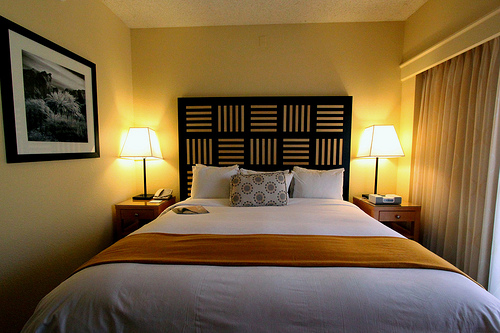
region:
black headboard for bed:
[168, 95, 369, 206]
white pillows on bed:
[161, 161, 368, 208]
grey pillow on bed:
[231, 164, 298, 214]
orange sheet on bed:
[62, 243, 429, 287]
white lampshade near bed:
[354, 108, 399, 180]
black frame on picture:
[0, 11, 134, 143]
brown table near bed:
[85, 181, 163, 245]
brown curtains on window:
[394, 84, 494, 304]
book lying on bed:
[167, 204, 218, 219]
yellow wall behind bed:
[232, 28, 306, 82]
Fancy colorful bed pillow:
[225, 164, 298, 206]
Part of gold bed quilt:
[170, 243, 268, 262]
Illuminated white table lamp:
[114, 124, 164, 196]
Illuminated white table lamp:
[354, 122, 409, 198]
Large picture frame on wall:
[0, 17, 102, 164]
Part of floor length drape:
[419, 83, 471, 155]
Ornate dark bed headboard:
[169, 91, 354, 167]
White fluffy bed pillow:
[291, 165, 348, 202]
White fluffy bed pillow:
[189, 161, 241, 196]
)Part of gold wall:
[24, 188, 80, 238]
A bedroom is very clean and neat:
[1, 1, 498, 330]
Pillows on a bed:
[188, 158, 349, 214]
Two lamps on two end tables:
[110, 120, 428, 224]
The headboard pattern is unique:
[172, 92, 354, 205]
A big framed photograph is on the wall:
[0, 14, 105, 167]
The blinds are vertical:
[396, 5, 498, 300]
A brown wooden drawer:
[117, 205, 155, 223]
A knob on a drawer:
[390, 210, 405, 223]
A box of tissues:
[365, 191, 404, 209]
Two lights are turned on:
[114, 122, 407, 164]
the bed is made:
[22, 165, 499, 330]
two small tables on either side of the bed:
[24, 175, 496, 332]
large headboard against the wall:
[160, 84, 364, 211]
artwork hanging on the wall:
[0, 17, 114, 173]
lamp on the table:
[112, 123, 173, 238]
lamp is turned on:
[354, 120, 407, 205]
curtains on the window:
[404, 35, 499, 295]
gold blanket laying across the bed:
[65, 220, 481, 301]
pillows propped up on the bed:
[179, 156, 348, 213]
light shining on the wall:
[107, 78, 169, 126]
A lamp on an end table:
[353, 121, 426, 245]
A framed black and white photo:
[1, 14, 102, 164]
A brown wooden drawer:
[375, 206, 417, 226]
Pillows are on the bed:
[185, 158, 349, 212]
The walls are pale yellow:
[1, 1, 498, 329]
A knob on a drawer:
[129, 205, 145, 223]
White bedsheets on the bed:
[19, 196, 498, 330]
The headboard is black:
[174, 92, 354, 202]